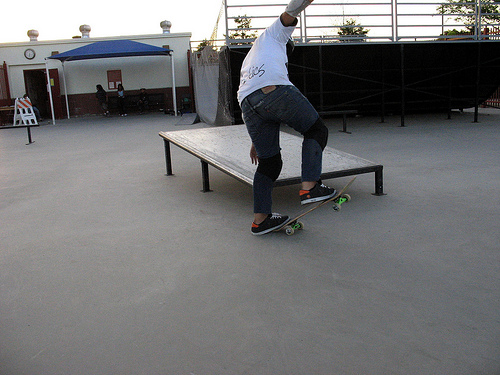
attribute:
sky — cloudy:
[1, 2, 469, 38]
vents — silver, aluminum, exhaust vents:
[19, 19, 194, 38]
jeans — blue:
[216, 90, 401, 220]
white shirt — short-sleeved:
[232, 22, 294, 107]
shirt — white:
[236, 15, 298, 103]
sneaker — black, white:
[296, 180, 338, 205]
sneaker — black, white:
[251, 213, 290, 235]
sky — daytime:
[2, 2, 428, 39]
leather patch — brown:
[256, 83, 280, 97]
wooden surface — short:
[153, 109, 405, 222]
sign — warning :
[10, 94, 42, 135]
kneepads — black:
[236, 116, 332, 184]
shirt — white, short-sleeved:
[219, 16, 309, 108]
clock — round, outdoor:
[25, 47, 37, 62]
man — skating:
[215, 12, 357, 249]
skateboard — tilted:
[253, 170, 356, 245]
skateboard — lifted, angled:
[269, 174, 359, 236]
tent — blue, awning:
[49, 23, 158, 98]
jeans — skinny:
[246, 87, 334, 205]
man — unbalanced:
[166, 0, 384, 230]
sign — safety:
[7, 95, 37, 130]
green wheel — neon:
[334, 201, 341, 212]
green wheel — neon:
[346, 195, 351, 204]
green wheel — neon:
[285, 229, 292, 234]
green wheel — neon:
[295, 220, 304, 231]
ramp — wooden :
[166, 98, 397, 215]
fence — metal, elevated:
[235, 6, 449, 74]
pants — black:
[235, 79, 323, 208]